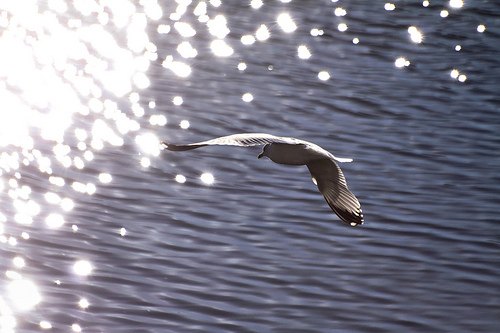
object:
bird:
[158, 129, 365, 228]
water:
[0, 0, 499, 333]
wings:
[305, 160, 365, 227]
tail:
[331, 154, 355, 162]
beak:
[256, 151, 267, 159]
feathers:
[318, 159, 365, 226]